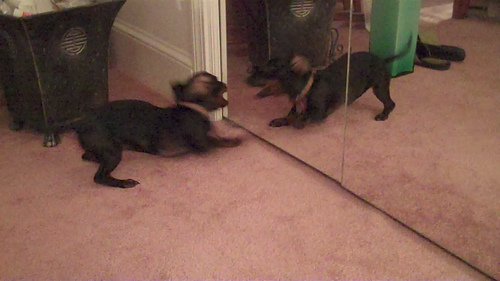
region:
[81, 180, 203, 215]
black spot on pink carpet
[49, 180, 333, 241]
large patch of pink carpet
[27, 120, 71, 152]
black foot of drawer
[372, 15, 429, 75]
large square green post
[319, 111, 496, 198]
clear mirror with line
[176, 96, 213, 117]
light brown collar around dog's neck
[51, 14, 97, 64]
tan circle in brown drawer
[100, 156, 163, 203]
dog's foot on pink carpet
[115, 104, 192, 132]
black shiny coat on dot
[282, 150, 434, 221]
straight lines at bottom of mirrors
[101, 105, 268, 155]
the dog is black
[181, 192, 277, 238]
the floor is carpeted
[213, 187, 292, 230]
the floor is brown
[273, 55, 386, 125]
there is a dog reflection onthe mirror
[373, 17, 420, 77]
the container is green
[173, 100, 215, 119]
the dog has a brown colar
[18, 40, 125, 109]
the trash container is black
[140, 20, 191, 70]
the wall is white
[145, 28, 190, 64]
the wall is made of wood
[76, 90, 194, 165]
the dog is black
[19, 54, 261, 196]
A dog in front of a mirror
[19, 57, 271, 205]
Dog is dark brown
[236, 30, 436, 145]
Reflection of a dog in the mirror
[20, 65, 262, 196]
Dog is barking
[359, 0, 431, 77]
A column reflected in a mirror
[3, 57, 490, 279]
Floor is pink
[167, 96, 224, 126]
Dog has a collar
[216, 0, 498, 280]
Big mirror in a wall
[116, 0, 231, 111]
Wall is white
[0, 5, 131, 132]
Piece of furniture next to dog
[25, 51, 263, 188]
a small black and brown dog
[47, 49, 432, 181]
dog playing with the mirror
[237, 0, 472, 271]
a mirror covered sliding door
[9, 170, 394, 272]
a bright pink carpet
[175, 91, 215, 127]
a red and pink dog collar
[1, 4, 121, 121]
a decorative metal trash can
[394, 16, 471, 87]
a pair of flip flops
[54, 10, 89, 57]
a decorative metal emblem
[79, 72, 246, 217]
dog with short legs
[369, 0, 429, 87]
a green bag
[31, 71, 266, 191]
dog barking at mirror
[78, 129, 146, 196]
back right leg of dog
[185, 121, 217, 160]
front right leg of dog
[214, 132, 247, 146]
front left leg of dog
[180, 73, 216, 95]
right ear of dog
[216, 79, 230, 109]
open mouth of dog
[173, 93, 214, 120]
collar on barking dog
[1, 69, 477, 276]
pink carpet in a room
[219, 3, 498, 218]
glass doors in a room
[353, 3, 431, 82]
reflection of a green object in a mirror